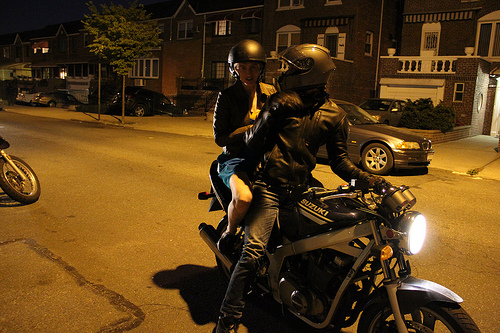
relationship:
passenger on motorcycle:
[212, 40, 279, 253] [196, 161, 478, 331]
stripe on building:
[405, 11, 472, 22] [388, 0, 498, 138]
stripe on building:
[405, 11, 472, 22] [378, 0, 498, 145]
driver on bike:
[216, 43, 395, 333] [192, 120, 498, 329]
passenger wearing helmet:
[209, 38, 276, 256] [221, 34, 276, 86]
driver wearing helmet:
[210, 43, 392, 331] [276, 42, 335, 94]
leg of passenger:
[220, 166, 253, 238] [216, 44, 398, 329]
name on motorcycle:
[297, 197, 331, 219] [196, 161, 478, 331]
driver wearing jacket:
[216, 43, 395, 333] [233, 88, 380, 191]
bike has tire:
[197, 159, 481, 333] [361, 282, 481, 330]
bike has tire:
[0, 136, 41, 202] [2, 147, 38, 216]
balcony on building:
[397, 55, 455, 76] [378, 0, 500, 144]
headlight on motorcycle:
[388, 203, 438, 263] [263, 167, 459, 330]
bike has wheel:
[197, 159, 481, 333] [5, 147, 46, 209]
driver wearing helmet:
[216, 43, 395, 333] [271, 48, 345, 100]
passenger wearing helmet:
[212, 40, 279, 253] [225, 37, 272, 67]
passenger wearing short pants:
[212, 40, 279, 253] [210, 152, 241, 182]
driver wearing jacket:
[216, 43, 395, 333] [230, 63, 376, 215]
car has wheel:
[323, 97, 430, 169] [360, 140, 390, 174]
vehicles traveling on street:
[217, 61, 464, 331] [30, 120, 209, 282]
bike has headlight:
[147, 101, 478, 331] [394, 211, 426, 256]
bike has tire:
[194, 156, 484, 331] [354, 279, 484, 331]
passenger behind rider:
[212, 40, 279, 253] [217, 44, 405, 329]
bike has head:
[197, 159, 481, 333] [284, 47, 324, 91]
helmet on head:
[277, 43, 337, 89] [284, 47, 324, 91]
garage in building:
[359, 63, 456, 147] [378, 0, 500, 144]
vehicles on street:
[3, 55, 213, 124] [1, 114, 497, 329]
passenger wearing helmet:
[212, 40, 279, 253] [213, 28, 282, 101]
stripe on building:
[405, 11, 472, 22] [394, 26, 464, 76]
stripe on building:
[402, 12, 473, 21] [378, 0, 498, 145]